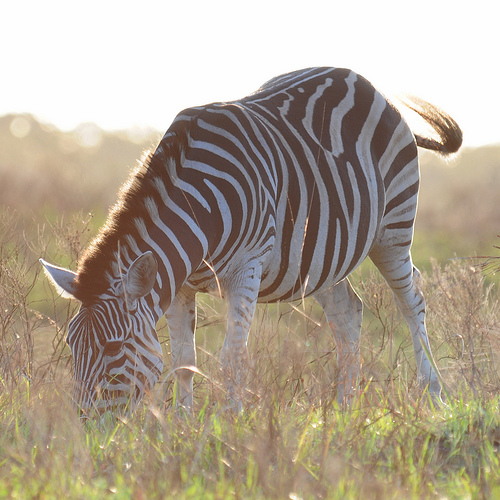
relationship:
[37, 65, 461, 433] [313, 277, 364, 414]
zebra has leg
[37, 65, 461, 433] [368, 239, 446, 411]
zebra has leg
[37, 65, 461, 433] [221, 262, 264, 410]
zebra has leg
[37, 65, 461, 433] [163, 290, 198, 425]
zebra has leg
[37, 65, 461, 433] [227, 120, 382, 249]
zebra has stripes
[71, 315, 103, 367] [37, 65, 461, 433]
forehead of zebra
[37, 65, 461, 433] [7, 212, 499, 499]
zebra in a field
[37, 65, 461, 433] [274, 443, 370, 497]
zebra in grass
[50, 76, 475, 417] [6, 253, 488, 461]
zebra eating grass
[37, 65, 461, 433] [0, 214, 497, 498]
zebra eating grass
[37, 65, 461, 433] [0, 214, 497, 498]
zebra cropping grass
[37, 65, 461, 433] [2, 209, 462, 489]
zebra standing in forest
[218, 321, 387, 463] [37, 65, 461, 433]
legs of zebra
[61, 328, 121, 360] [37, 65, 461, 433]
eyes of zebra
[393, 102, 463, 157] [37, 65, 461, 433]
tail of zebra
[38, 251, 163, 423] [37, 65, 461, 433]
head of zebra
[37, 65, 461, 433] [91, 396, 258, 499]
zebra eating grass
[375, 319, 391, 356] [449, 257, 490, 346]
stems on weeds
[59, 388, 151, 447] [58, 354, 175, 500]
mouth of zebra covered by grass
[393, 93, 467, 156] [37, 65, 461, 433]
tail of zebra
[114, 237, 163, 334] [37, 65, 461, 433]
ear of a zebra